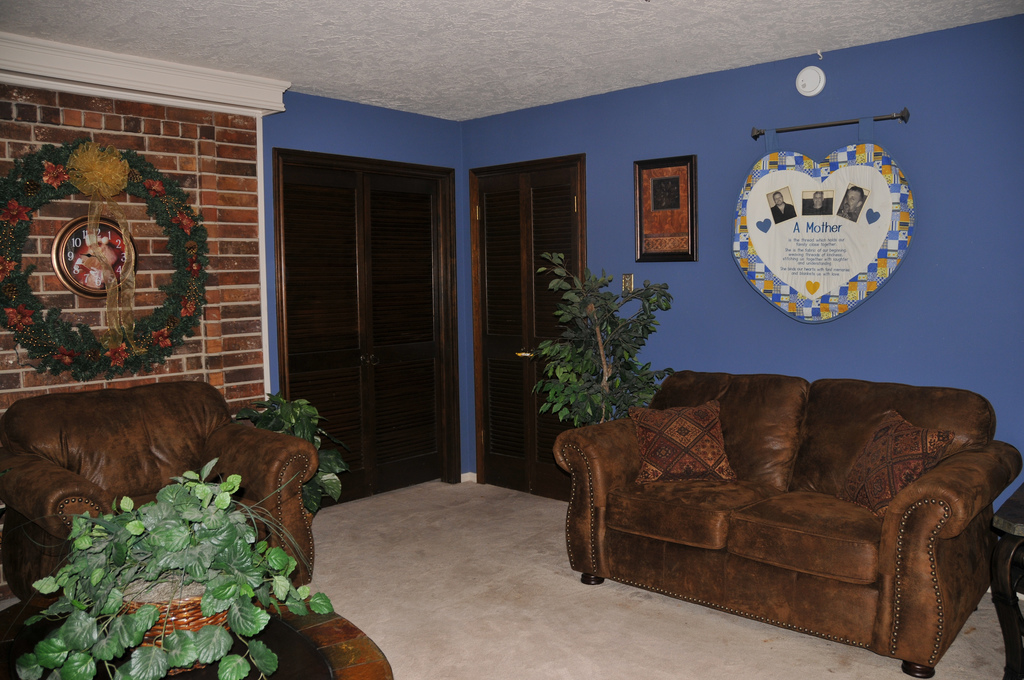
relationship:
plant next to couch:
[530, 247, 677, 431] [552, 372, 1019, 675]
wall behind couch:
[455, 14, 1017, 485] [552, 372, 1019, 675]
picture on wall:
[632, 154, 697, 261] [455, 14, 1017, 485]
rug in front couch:
[356, 523, 458, 610] [593, 366, 976, 648]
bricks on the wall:
[207, 323, 246, 363] [146, 121, 248, 178]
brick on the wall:
[202, 208, 237, 260] [207, 158, 259, 312]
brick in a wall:
[220, 297, 255, 350] [189, 139, 244, 246]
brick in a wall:
[217, 262, 244, 299] [228, 204, 259, 274]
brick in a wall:
[226, 255, 259, 307] [206, 109, 284, 354]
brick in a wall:
[198, 176, 235, 203] [206, 130, 284, 360]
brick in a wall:
[215, 234, 242, 254] [196, 148, 253, 313]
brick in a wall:
[213, 143, 231, 163] [202, 143, 252, 280]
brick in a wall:
[202, 152, 242, 168] [200, 109, 255, 332]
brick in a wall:
[202, 152, 248, 178] [187, 135, 265, 330]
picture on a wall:
[632, 154, 697, 261] [913, 59, 980, 142]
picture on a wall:
[632, 154, 697, 261] [690, 104, 716, 133]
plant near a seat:
[529, 247, 676, 442] [570, 351, 972, 647]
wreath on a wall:
[40, 126, 205, 364] [185, 128, 229, 178]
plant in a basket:
[103, 510, 242, 571] [163, 586, 202, 625]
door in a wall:
[481, 217, 538, 378] [600, 117, 648, 159]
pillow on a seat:
[645, 418, 713, 475] [576, 318, 970, 643]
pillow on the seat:
[621, 396, 741, 486] [565, 363, 957, 632]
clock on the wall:
[58, 201, 138, 288] [135, 234, 172, 271]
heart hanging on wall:
[736, 160, 914, 320] [922, 121, 966, 240]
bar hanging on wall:
[738, 107, 942, 140] [958, 89, 991, 157]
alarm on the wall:
[772, 53, 842, 97] [911, 63, 953, 161]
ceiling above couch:
[388, 29, 488, 56] [613, 370, 933, 610]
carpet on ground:
[481, 541, 594, 624] [343, 474, 726, 675]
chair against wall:
[13, 404, 325, 586] [4, 234, 277, 448]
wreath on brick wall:
[0, 137, 212, 384] [26, 80, 297, 426]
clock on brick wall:
[48, 212, 143, 301] [24, 91, 254, 381]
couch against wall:
[576, 351, 1017, 669] [616, 85, 1018, 453]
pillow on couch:
[621, 396, 741, 486] [561, 329, 991, 675]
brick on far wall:
[192, 136, 260, 191] [104, 124, 316, 423]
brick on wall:
[188, 175, 236, 201] [58, 89, 294, 409]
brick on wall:
[192, 186, 253, 234] [71, 95, 333, 459]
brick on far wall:
[186, 223, 286, 267] [110, 100, 316, 446]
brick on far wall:
[188, 212, 249, 247] [131, 119, 292, 457]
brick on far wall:
[194, 214, 249, 234] [131, 130, 261, 442]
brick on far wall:
[181, 258, 275, 308] [103, 96, 266, 440]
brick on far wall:
[199, 273, 269, 312] [60, 128, 303, 431]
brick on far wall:
[188, 281, 297, 323] [88, 89, 315, 409]